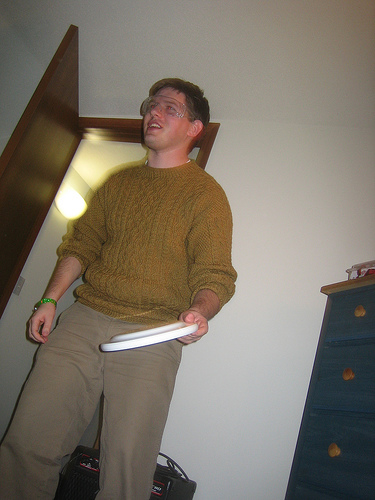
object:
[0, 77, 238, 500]
man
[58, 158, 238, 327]
sweater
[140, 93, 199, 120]
goggles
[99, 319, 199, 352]
frisbee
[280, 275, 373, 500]
dresser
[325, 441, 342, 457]
knobs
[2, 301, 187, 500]
pants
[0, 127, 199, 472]
doorway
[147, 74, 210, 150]
hair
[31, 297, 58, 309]
watch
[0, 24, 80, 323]
door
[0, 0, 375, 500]
wall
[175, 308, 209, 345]
hand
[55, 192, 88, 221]
light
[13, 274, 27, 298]
switch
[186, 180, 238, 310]
sleeve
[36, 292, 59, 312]
wrist